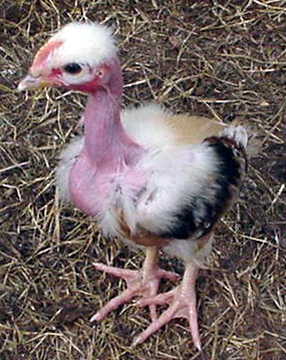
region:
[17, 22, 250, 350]
ugly Duckling on the ground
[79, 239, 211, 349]
two thin duck legs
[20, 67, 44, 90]
little peak of duck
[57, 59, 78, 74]
small black left eye of duck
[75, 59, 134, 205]
large featherless neck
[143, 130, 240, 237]
small feathered left wing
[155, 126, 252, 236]
black feathers on left wing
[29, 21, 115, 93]
red and white little head of duck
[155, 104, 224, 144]
light brown feathers on duck tail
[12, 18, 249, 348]
small white and black featherless duck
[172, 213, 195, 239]
part of the birds feathers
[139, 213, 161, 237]
part of the birds feathers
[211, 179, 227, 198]
part of the birds feathers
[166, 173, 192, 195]
part of the birds feathers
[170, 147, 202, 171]
part of the birds feathers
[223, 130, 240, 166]
part of the birds feathers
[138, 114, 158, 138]
part of the birds feathers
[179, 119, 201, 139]
part of the birds feathers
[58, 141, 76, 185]
part of the birds feathers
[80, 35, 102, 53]
part of the birds feathers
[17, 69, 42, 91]
one pointy light colored bird beak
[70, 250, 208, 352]
two small light colored bird feet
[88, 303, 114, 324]
one lone light colored bird talon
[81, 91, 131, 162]
one pink small bird neck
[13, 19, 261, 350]
one young black and white bird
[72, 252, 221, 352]
two bird feet in dirt and hay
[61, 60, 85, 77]
one almond shaped dark bird eye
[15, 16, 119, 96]
one baby bird head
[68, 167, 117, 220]
one small pink bird breast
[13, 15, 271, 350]
small bird standing in bits of hay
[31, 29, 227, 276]
baby bird standing on grass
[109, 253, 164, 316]
pink foot of baby bird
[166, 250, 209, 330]
pink foot of baby bird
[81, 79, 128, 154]
pink neck of baby bird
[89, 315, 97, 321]
small nail on end of foot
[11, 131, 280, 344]
brown grass on ground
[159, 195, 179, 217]
white fur on bird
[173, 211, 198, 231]
black fur on bird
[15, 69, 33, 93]
small beak on bird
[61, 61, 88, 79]
small eye of bird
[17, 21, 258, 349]
a baby turkey standing on some straw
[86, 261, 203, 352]
the pink feet of a baby turkey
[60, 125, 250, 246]
the body of a small young turkey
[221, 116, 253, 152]
the tiny tail of a baby turkey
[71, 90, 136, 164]
the bare pink neck of a baby turkey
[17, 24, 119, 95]
the head of a little baby turkey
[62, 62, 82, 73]
the black eye of a baby turkey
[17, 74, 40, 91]
the tiny beak of a newly hatched turkey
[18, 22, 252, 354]
a newly-hatched baby tukey standing on straw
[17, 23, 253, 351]
a baby bird with a few downy feathers